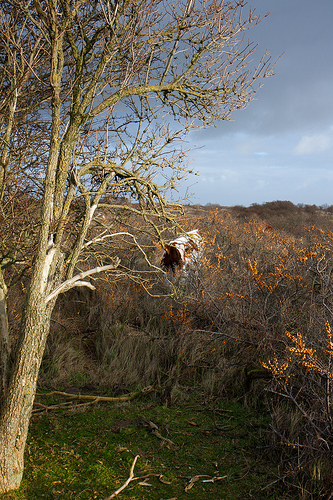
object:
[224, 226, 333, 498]
bushes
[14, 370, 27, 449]
bark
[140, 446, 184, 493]
ground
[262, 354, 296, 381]
leaves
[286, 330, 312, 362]
leaves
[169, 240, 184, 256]
patch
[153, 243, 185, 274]
cow's face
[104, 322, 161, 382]
grass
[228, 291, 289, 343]
bush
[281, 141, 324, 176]
clouds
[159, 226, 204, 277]
cow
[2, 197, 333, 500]
forest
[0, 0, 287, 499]
tree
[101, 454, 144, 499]
branch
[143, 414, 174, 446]
branch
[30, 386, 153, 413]
branch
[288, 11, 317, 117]
blue sky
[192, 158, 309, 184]
white clouds